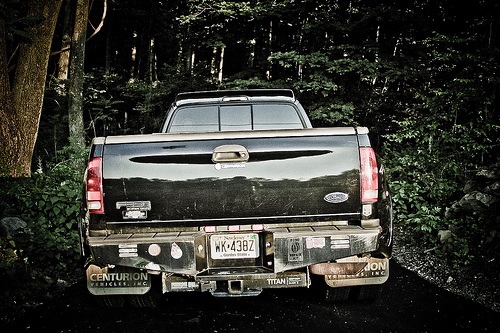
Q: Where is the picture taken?
A: Woods.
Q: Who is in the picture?
A: No one.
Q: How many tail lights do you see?
A: 2.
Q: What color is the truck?
A: Black.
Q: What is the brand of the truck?
A: Ford.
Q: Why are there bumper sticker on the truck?
A: For fun.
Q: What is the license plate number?
A: WK 438Z.